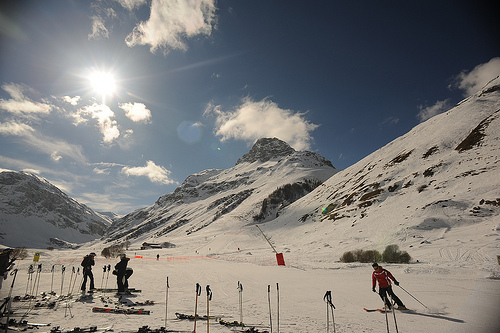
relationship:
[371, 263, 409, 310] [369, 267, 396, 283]
people in a coat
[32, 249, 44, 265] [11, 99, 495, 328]
sign in snow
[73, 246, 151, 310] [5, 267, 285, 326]
people among ski poles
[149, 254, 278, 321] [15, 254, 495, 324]
tracks in snow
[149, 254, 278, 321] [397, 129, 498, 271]
tracks in snow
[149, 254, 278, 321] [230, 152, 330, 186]
tracks in snow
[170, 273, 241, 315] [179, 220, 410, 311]
poles in snow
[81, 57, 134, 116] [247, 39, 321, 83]
bright sun in sky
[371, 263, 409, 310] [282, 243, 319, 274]
people zooming through snow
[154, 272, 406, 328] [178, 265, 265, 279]
poles in snow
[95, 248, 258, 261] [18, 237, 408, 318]
boundaries in snow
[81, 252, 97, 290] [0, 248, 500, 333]
man walking on ground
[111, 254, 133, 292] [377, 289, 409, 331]
people standing near poles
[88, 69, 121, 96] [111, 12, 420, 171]
bright sun shining in sky